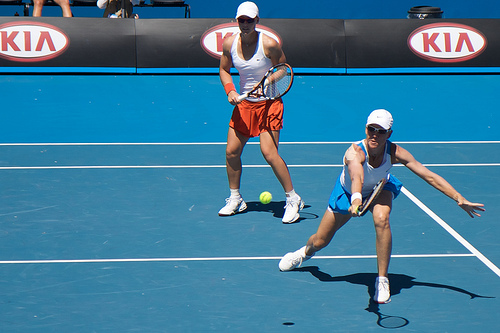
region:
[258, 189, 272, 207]
tennis ball is in play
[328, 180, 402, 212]
woman wears a blue skirt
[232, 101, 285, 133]
man wears orange shorts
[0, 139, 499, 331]
a blue tennis court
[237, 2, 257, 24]
white cap with a sun visor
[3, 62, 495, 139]
a blu wall behind the court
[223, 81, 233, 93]
orange wrist band on the man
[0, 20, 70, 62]
KIA on the wall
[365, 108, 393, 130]
white hat on the player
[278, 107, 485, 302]
player wearing the white hat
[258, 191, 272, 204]
the green tennis ball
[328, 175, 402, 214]
the blue tennis skirt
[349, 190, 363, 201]
the white wristband on the arm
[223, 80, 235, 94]
the orange wristband on the arm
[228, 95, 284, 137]
the orange tennis skirt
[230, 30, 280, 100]
the white tanktop on the woman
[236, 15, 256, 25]
the sunglasses on the woman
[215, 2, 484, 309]
Two people are playing tennis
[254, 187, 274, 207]
A round tennis ball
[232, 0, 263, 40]
White hat on man's head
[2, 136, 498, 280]
White lines on the tennis court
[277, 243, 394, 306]
A pair of white sneakers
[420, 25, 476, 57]
"KIA" written in red letters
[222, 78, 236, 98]
An orange arm band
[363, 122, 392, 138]
A pair of sunglasses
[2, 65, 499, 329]
A blue tennis court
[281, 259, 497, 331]
Shadow on the court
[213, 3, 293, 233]
Man on a tenis court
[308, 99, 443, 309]
Woman on a tennis court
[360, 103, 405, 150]
Woman wearing a white hat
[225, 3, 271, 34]
Woman wearing a white hat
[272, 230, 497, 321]
Shadow of lady on the ground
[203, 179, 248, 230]
White shoe and sock on foot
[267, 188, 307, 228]
White shoe and sock on foot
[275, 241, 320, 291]
White shoe and sock on foot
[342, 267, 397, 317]
White shoe and sock on foot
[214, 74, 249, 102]
Orange wrist band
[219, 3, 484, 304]
people are playing tennis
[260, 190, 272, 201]
ball in the air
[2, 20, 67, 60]
kia logo on wall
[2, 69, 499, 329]
the court is blue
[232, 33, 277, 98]
the shirt is white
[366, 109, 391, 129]
the hat is white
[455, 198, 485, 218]
hand of a man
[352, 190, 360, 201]
wrist band is white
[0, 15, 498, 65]
the barrier is black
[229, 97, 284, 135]
the shorts are orange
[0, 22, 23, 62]
red letter on black wall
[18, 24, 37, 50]
red letter on black wall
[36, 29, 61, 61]
red letter on black wall